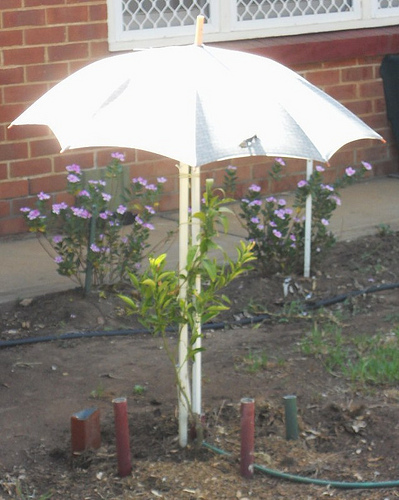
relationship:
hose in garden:
[214, 418, 326, 462] [163, 366, 334, 482]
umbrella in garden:
[94, 74, 262, 168] [163, 366, 334, 482]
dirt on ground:
[101, 353, 142, 379] [38, 324, 132, 382]